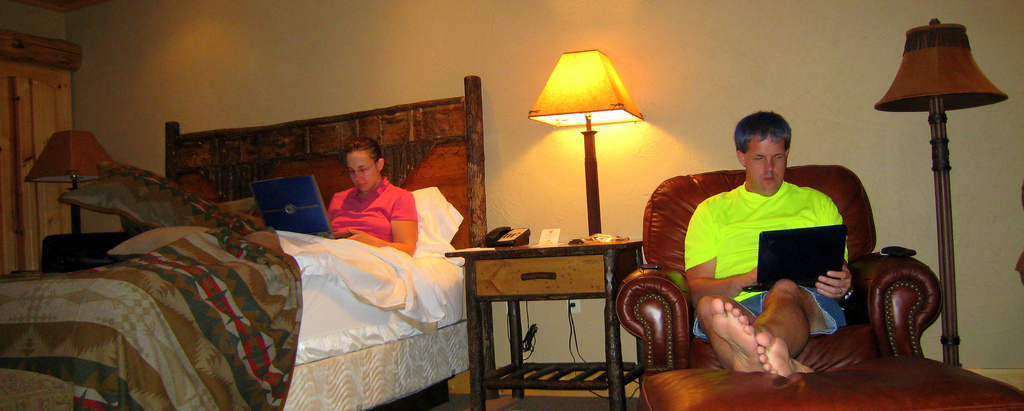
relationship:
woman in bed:
[233, 169, 428, 284] [168, 253, 443, 368]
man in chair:
[681, 109, 857, 378] [613, 163, 1022, 408]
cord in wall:
[513, 297, 619, 362] [468, 145, 697, 403]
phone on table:
[468, 201, 546, 264] [455, 201, 691, 359]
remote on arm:
[857, 229, 942, 275] [807, 225, 1004, 381]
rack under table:
[466, 363, 691, 403] [433, 234, 628, 390]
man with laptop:
[681, 109, 857, 378] [708, 230, 884, 328]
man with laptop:
[286, 134, 455, 256] [161, 141, 354, 267]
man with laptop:
[681, 109, 857, 378] [723, 236, 920, 334]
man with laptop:
[681, 109, 857, 378] [745, 212, 867, 314]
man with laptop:
[681, 109, 857, 378] [695, 201, 836, 297]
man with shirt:
[681, 109, 857, 378] [684, 184, 890, 312]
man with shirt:
[681, 109, 857, 378] [684, 180, 829, 362]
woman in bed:
[322, 142, 428, 241] [94, 78, 484, 396]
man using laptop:
[680, 109, 856, 378] [752, 221, 854, 286]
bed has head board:
[5, 72, 500, 407] [161, 77, 488, 248]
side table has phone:
[443, 234, 645, 407] [484, 226, 533, 247]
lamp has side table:
[526, 46, 645, 241] [443, 234, 645, 407]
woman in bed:
[322, 142, 428, 241] [4, 72, 499, 407]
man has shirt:
[680, 109, 856, 378] [678, 180, 853, 299]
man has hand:
[680, 109, 856, 378] [818, 262, 857, 302]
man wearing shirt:
[681, 109, 857, 378] [678, 180, 853, 299]